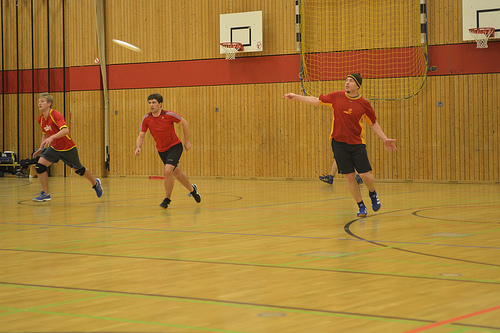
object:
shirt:
[316, 91, 379, 146]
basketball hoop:
[219, 41, 242, 61]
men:
[127, 86, 205, 208]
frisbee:
[110, 37, 143, 55]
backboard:
[217, 9, 267, 55]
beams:
[10, 2, 71, 182]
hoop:
[467, 26, 491, 50]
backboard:
[458, 0, 499, 45]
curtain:
[96, 1, 113, 174]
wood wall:
[201, 92, 291, 147]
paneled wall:
[0, 0, 500, 180]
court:
[0, 183, 500, 333]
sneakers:
[31, 191, 53, 202]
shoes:
[158, 197, 173, 210]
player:
[128, 87, 205, 212]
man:
[24, 94, 107, 204]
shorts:
[331, 139, 372, 175]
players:
[28, 90, 107, 203]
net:
[294, 0, 428, 102]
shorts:
[156, 142, 183, 167]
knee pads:
[34, 162, 48, 175]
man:
[285, 70, 398, 221]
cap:
[346, 72, 364, 87]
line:
[3, 36, 498, 93]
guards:
[33, 162, 49, 174]